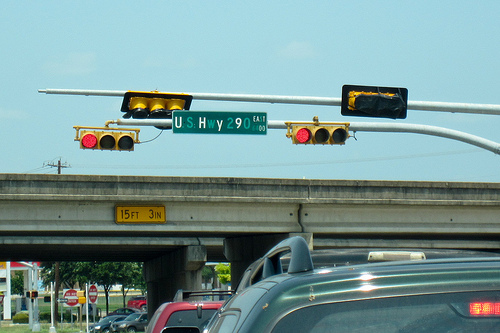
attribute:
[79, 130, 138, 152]
traffic light — red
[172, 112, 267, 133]
street sign — green, white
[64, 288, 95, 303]
sign — red, white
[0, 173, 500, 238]
bridge — grey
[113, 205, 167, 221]
sign — yellow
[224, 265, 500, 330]
minivan — green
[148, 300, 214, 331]
van — red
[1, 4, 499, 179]
sky — blue, clear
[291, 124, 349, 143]
traffic light — red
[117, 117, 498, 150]
pole — metal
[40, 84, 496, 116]
pole — metal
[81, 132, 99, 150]
light — red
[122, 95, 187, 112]
street light — yellow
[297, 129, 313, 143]
light — red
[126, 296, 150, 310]
car — red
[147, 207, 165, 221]
letters on sign — black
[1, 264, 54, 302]
building — white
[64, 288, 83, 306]
do not enter sign — red